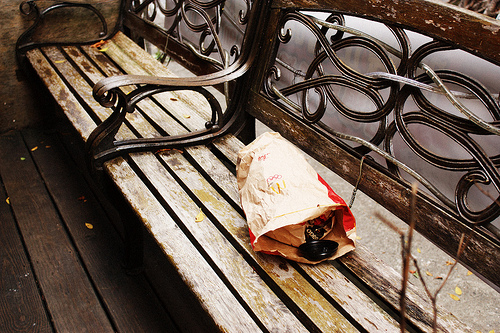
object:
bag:
[235, 132, 356, 265]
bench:
[14, 0, 497, 332]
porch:
[3, 121, 209, 332]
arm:
[86, 57, 241, 170]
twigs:
[372, 179, 473, 332]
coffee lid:
[298, 240, 339, 262]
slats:
[127, 130, 404, 332]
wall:
[1, 0, 123, 137]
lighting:
[267, 15, 499, 237]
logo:
[267, 174, 286, 194]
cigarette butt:
[31, 142, 41, 159]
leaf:
[93, 37, 108, 57]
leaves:
[7, 133, 99, 234]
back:
[254, 1, 499, 267]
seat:
[117, 141, 455, 332]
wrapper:
[264, 210, 335, 248]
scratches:
[133, 154, 242, 231]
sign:
[318, 173, 357, 232]